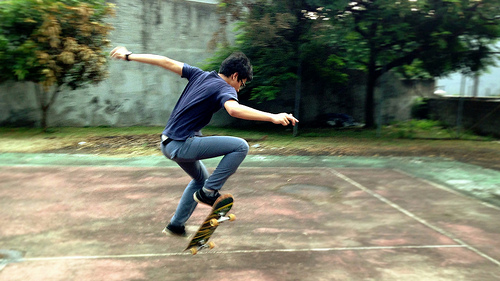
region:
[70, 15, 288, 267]
the man is skateboarding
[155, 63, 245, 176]
the shirt is blue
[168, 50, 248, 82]
boy has brown hair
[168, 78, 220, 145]
boy has blue shirt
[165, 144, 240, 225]
boy has blue pants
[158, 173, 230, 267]
boy has black shoes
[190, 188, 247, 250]
orange and black skateboard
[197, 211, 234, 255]
tan wheels on skateboard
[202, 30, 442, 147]
green trees behind boy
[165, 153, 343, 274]
boy jumps on board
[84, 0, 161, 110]
grey wall behind boy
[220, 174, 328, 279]
concrete is brown and orange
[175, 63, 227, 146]
the shirt is blue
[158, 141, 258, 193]
the jeans are green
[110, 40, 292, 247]
the skater is in air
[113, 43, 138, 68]
watch is on the wrist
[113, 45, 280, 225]
the man has glasses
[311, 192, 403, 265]
the court is brown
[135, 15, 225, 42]
the wall is dirty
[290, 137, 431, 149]
leaves are on the grass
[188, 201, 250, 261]
the wheels are yellow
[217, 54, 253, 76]
the hair is black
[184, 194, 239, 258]
a skateboard on the air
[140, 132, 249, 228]
a man wearing jeans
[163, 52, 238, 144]
his shirt is dark blue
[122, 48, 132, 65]
a watch on his left wrist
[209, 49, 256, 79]
his hair is black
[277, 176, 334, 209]
a puddle on the pavement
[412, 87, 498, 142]
a wall right of the pavement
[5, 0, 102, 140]
a tree by the wall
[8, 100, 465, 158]
grass behind the pavement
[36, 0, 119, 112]
these trees are brown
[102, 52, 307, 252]
man riding a skateboard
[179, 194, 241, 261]
skateboard with a black and yellow deck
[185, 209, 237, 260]
yellow wheels on a skateboard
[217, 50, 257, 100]
man with short black hair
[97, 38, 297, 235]
man wearing a blue shirt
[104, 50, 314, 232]
man wearing blue pants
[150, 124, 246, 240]
long blue pants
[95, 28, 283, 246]
man wearing black shoes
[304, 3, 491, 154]
tree with green leaves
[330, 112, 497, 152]
grass growing next to tree